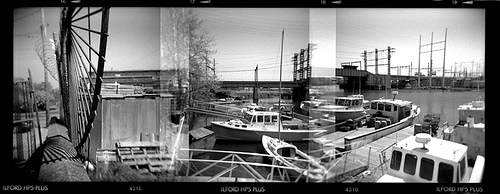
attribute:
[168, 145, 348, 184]
guardrail — metal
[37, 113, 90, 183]
rail — thick, concrete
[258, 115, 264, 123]
window — glass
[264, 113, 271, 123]
window — glass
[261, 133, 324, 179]
boat — small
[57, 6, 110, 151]
wheel — large, spoked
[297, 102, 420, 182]
pier — wooden, plank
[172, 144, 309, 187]
fencing — metal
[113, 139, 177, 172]
pallets — wooden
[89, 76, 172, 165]
shack — wooden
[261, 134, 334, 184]
boat — small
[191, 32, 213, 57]
branch — leafless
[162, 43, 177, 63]
branch — leafless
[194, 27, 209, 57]
branch — leafless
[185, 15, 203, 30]
branch — leafless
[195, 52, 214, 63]
branch — leafless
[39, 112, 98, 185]
rail — concrete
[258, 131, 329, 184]
boat — small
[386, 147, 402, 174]
window — glass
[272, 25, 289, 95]
power pole — tall